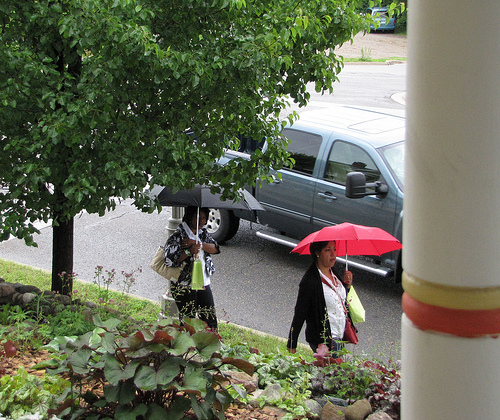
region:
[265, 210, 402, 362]
woman with red umbrella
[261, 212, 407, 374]
woman with umbrella in left hand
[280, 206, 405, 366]
woman with purse on shoulder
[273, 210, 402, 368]
woman wearing an earring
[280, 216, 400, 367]
person carrying an umbrella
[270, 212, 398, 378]
person carrying a red umbrella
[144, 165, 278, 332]
person with a black umbrella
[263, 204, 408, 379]
woman walking in the rain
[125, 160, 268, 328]
person with purse on shoulder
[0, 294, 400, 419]
foliage above the sidewalk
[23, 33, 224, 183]
a green full tree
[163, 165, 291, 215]
a plain black umbrella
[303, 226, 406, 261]
a red short umbrella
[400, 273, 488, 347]
a yellow and red ringed pole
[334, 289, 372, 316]
woman holding a green bag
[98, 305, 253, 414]
a red and grean leaf plant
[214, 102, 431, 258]
a icy blue colored truck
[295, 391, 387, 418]
a brown pile of rocks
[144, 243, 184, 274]
a tan and white bag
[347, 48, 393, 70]
a yellow curb with a plant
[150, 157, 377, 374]
Two woman walking down the street.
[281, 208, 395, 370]
Woman with red umbrella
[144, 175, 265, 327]
Woman with black umbrella.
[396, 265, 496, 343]
Two colored stripes on column.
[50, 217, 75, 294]
Trunk of leafy tree.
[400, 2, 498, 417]
White column with two stripes on it.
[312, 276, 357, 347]
Red purse with strap.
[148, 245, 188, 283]
Light beige square purse.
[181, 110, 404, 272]
Stone grey truck in road.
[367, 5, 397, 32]
The back of a blue parked car.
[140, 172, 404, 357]
Two women holding umbrellas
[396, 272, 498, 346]
Red and yellow stripe on post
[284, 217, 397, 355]
Woman holding a red umbrella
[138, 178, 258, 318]
Woman holding a black umbrella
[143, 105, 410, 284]
Truck on the street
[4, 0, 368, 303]
Tree alongside the street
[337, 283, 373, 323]
Yellow bag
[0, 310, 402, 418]
Plants along the pathway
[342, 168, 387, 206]
Side-view mirror on truck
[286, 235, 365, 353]
Woman with white shirt and black jacket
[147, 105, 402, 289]
A truck parked down on the road.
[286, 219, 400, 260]
A red umbrella a woman is carrying.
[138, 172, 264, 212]
Black opened top of an umbrella.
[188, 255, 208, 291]
Small lime green bag a woman is carrying who has a black umbrella.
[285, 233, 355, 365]
Woman in black coat holding a red umbrella.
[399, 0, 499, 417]
White pole with yellow and red stripes towards the bottom.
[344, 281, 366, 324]
Small lime green bag a woman with a red umbrella is holding.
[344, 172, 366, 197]
Large black back of a passenger side rear view mirror on a truck.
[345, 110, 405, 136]
Sunroof on top of a truck.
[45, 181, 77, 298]
Brown tree trunk behind a woman carrying a black umbrella.